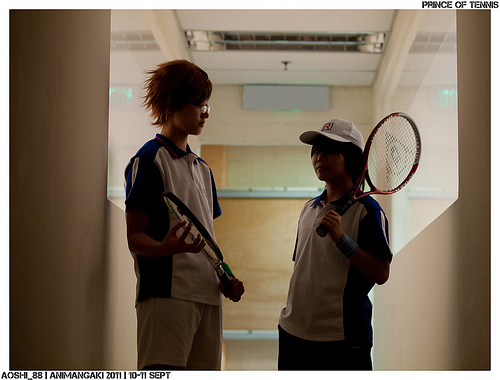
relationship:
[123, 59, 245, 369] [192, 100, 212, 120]
boy wearing specs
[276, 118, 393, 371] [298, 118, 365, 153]
boy wearing cap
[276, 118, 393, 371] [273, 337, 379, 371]
boy wearing pant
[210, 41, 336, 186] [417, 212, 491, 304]
building has wall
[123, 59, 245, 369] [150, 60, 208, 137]
boy has head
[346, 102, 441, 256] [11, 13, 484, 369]
racket shown in photo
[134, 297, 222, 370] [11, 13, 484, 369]
shorts shown in photo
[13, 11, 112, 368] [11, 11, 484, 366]
pillar supporting building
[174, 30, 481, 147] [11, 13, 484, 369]
ceiling shown in photo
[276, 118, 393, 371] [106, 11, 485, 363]
boy standing in hallway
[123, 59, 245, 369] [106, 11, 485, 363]
boy standing in hallway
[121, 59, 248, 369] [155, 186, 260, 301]
boy holding racket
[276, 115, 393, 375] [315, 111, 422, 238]
boy holding racket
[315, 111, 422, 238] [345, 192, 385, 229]
racket leaning on shoulder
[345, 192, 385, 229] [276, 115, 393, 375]
shoulder belonging to boy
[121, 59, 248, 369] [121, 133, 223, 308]
boy wearing jersey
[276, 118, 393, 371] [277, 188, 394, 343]
boy wearing shirt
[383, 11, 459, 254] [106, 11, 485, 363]
window hanging in hallway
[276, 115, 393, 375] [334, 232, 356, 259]
boy wearing wristband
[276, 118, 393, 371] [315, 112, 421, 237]
boy holding racket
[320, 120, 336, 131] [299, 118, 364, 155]
logo sewn on hat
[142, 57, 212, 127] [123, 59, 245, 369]
hair belonging to boy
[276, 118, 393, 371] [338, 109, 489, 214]
boy holding racket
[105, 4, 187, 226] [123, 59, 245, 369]
window behind boy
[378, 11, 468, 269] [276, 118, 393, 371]
window behind boy